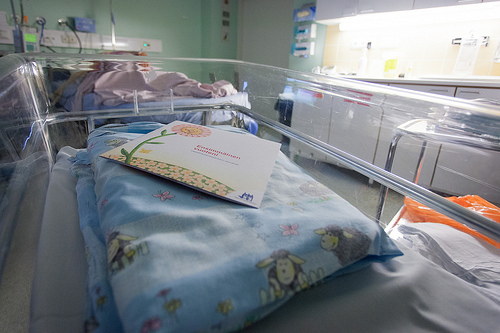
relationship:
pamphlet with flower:
[97, 115, 284, 214] [167, 117, 212, 140]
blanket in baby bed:
[66, 120, 404, 332] [0, 50, 498, 321]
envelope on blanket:
[121, 120, 267, 205] [101, 180, 266, 300]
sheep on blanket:
[254, 248, 318, 296] [87, 116, 372, 331]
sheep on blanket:
[320, 215, 371, 271] [87, 116, 372, 331]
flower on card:
[171, 124, 213, 138] [98, 120, 283, 209]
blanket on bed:
[73, 55, 240, 116] [46, 45, 255, 132]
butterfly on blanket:
[271, 217, 304, 242] [73, 112, 408, 328]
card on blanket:
[95, 114, 282, 209] [73, 112, 408, 328]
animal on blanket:
[253, 250, 310, 292] [73, 112, 408, 328]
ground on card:
[303, 197, 326, 224] [95, 114, 282, 209]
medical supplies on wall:
[3, 0, 163, 57] [0, 1, 237, 80]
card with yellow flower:
[95, 114, 282, 209] [118, 115, 211, 170]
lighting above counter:
[322, 2, 497, 42] [306, 65, 499, 89]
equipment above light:
[73, 15, 96, 36] [101, 35, 129, 52]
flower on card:
[171, 124, 213, 138] [95, 114, 282, 209]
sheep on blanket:
[246, 258, 301, 290] [184, 201, 318, 312]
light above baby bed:
[128, 12, 189, 92] [1, 49, 499, 330]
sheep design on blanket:
[235, 217, 397, 314] [73, 112, 408, 328]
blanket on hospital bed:
[73, 55, 240, 116] [43, 60, 263, 134]